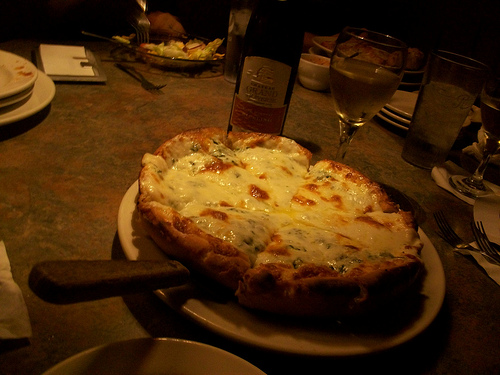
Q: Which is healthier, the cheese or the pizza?
A: The cheese is healthier than the pizza.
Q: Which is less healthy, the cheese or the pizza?
A: The pizza is less healthy than the cheese.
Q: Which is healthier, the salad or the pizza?
A: The salad is healthier than the pizza.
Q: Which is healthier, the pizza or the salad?
A: The salad is healthier than the pizza.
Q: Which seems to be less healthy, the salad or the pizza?
A: The pizza is less healthy than the salad.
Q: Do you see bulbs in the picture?
A: No, there are no bulbs.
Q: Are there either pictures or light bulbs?
A: No, there are no light bulbs or pictures.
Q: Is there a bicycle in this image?
A: No, there are no bicycles.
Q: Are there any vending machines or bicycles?
A: No, there are no bicycles or vending machines.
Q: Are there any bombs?
A: No, there are no bombs.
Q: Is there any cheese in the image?
A: Yes, there is cheese.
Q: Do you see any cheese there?
A: Yes, there is cheese.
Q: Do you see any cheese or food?
A: Yes, there is cheese.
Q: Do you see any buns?
A: No, there are no buns.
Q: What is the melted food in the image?
A: The food is cheese.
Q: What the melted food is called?
A: The food is cheese.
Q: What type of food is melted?
A: The food is cheese.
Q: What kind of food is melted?
A: The food is cheese.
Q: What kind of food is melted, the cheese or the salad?
A: The cheese is melted.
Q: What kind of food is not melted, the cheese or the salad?
A: The salad is not melted.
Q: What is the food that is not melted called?
A: The food is salad.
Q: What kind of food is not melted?
A: The food is salad.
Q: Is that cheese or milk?
A: That is cheese.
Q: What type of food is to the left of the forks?
A: The food is cheese.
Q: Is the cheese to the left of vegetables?
A: No, the cheese is to the left of the forks.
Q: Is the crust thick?
A: Yes, the crust is thick.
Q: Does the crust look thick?
A: Yes, the crust is thick.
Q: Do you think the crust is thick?
A: Yes, the crust is thick.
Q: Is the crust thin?
A: No, the crust is thick.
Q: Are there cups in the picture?
A: Yes, there is a cup.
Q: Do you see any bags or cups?
A: Yes, there is a cup.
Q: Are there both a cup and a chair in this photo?
A: No, there is a cup but no chairs.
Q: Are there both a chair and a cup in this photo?
A: No, there is a cup but no chairs.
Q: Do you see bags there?
A: No, there are no bags.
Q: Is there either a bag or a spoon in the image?
A: No, there are no bags or spoons.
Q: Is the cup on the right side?
A: Yes, the cup is on the right of the image.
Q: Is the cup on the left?
A: No, the cup is on the right of the image.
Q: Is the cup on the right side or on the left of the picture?
A: The cup is on the right of the image.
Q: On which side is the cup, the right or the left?
A: The cup is on the right of the image.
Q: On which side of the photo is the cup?
A: The cup is on the right of the image.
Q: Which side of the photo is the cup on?
A: The cup is on the right of the image.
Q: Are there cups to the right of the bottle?
A: Yes, there is a cup to the right of the bottle.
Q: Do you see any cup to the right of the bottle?
A: Yes, there is a cup to the right of the bottle.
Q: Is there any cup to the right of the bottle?
A: Yes, there is a cup to the right of the bottle.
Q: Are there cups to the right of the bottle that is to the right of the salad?
A: Yes, there is a cup to the right of the bottle.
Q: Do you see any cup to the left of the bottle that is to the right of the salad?
A: No, the cup is to the right of the bottle.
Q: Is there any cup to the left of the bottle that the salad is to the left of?
A: No, the cup is to the right of the bottle.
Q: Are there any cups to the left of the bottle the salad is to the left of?
A: No, the cup is to the right of the bottle.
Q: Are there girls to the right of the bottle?
A: No, there is a cup to the right of the bottle.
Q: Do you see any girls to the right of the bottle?
A: No, there is a cup to the right of the bottle.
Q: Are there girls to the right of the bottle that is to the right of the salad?
A: No, there is a cup to the right of the bottle.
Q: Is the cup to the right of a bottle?
A: Yes, the cup is to the right of a bottle.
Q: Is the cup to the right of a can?
A: No, the cup is to the right of a bottle.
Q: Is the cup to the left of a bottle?
A: No, the cup is to the right of a bottle.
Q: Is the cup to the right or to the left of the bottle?
A: The cup is to the right of the bottle.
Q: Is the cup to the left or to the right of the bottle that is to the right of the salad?
A: The cup is to the right of the bottle.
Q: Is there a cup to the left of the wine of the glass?
A: No, the cup is to the right of the wine.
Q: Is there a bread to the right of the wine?
A: No, there is a cup to the right of the wine.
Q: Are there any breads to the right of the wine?
A: No, there is a cup to the right of the wine.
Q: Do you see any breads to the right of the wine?
A: No, there is a cup to the right of the wine.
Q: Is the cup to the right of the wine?
A: Yes, the cup is to the right of the wine.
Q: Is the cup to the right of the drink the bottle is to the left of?
A: Yes, the cup is to the right of the wine.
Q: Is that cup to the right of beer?
A: No, the cup is to the right of the wine.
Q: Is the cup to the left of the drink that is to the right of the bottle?
A: No, the cup is to the right of the wine.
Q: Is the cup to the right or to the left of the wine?
A: The cup is to the right of the wine.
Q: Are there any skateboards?
A: No, there are no skateboards.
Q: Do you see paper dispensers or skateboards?
A: No, there are no skateboards or paper dispensers.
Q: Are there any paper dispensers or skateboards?
A: No, there are no skateboards or paper dispensers.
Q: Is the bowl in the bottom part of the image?
A: Yes, the bowl is in the bottom of the image.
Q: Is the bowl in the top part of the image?
A: No, the bowl is in the bottom of the image.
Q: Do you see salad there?
A: Yes, there is salad.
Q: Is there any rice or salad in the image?
A: Yes, there is salad.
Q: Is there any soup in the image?
A: No, there is no soup.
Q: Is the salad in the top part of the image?
A: Yes, the salad is in the top of the image.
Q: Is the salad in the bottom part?
A: No, the salad is in the top of the image.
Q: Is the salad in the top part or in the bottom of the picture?
A: The salad is in the top of the image.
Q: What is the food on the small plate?
A: The food is salad.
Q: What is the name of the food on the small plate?
A: The food is salad.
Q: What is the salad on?
A: The salad is on the plate.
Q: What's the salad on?
A: The salad is on the plate.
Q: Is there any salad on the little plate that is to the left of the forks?
A: Yes, there is salad on the plate.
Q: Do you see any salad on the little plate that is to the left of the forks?
A: Yes, there is salad on the plate.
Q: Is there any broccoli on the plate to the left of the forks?
A: No, there is salad on the plate.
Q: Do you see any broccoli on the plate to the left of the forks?
A: No, there is salad on the plate.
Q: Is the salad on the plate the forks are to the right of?
A: Yes, the salad is on the plate.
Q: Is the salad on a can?
A: No, the salad is on the plate.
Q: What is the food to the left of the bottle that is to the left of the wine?
A: The food is salad.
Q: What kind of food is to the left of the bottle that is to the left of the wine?
A: The food is salad.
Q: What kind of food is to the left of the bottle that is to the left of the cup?
A: The food is salad.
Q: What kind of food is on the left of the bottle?
A: The food is salad.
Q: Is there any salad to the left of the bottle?
A: Yes, there is salad to the left of the bottle.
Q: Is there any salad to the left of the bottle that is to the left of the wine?
A: Yes, there is salad to the left of the bottle.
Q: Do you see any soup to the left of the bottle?
A: No, there is salad to the left of the bottle.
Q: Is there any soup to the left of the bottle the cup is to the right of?
A: No, there is salad to the left of the bottle.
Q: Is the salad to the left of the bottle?
A: Yes, the salad is to the left of the bottle.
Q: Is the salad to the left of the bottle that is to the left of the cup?
A: Yes, the salad is to the left of the bottle.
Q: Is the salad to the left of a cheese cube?
A: No, the salad is to the left of the bottle.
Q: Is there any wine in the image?
A: Yes, there is wine.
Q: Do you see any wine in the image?
A: Yes, there is wine.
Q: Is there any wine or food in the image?
A: Yes, there is wine.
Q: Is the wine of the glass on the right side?
A: Yes, the wine is on the right of the image.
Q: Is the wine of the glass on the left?
A: No, the wine is on the right of the image.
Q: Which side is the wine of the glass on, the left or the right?
A: The wine is on the right of the image.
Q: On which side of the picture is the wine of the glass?
A: The wine is on the right of the image.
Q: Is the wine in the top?
A: Yes, the wine is in the top of the image.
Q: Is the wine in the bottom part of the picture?
A: No, the wine is in the top of the image.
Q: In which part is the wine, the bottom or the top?
A: The wine is in the top of the image.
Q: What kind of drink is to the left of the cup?
A: The drink is wine.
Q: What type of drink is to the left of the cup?
A: The drink is wine.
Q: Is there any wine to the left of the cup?
A: Yes, there is wine to the left of the cup.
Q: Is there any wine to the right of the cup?
A: No, the wine is to the left of the cup.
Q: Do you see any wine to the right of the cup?
A: No, the wine is to the left of the cup.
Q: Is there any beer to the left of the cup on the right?
A: No, there is wine to the left of the cup.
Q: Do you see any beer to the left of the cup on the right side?
A: No, there is wine to the left of the cup.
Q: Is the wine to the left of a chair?
A: No, the wine is to the left of the cup.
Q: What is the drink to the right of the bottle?
A: The drink is wine.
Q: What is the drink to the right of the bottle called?
A: The drink is wine.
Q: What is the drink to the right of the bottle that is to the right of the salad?
A: The drink is wine.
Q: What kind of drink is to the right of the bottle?
A: The drink is wine.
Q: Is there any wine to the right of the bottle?
A: Yes, there is wine to the right of the bottle.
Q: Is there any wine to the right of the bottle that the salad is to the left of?
A: Yes, there is wine to the right of the bottle.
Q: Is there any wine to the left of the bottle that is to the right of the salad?
A: No, the wine is to the right of the bottle.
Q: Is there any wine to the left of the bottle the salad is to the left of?
A: No, the wine is to the right of the bottle.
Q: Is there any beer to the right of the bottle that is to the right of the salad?
A: No, there is wine to the right of the bottle.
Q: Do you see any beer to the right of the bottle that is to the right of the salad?
A: No, there is wine to the right of the bottle.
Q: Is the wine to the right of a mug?
A: No, the wine is to the right of the bottle.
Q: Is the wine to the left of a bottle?
A: No, the wine is to the right of a bottle.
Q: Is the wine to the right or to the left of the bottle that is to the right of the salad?
A: The wine is to the right of the bottle.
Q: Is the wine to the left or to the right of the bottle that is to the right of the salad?
A: The wine is to the right of the bottle.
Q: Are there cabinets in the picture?
A: No, there are no cabinets.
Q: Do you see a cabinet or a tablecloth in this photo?
A: No, there are no cabinets or tablecloths.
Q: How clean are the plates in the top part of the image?
A: The plates are dirty.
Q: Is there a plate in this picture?
A: Yes, there is a plate.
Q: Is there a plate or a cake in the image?
A: Yes, there is a plate.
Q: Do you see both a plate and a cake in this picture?
A: No, there is a plate but no cakes.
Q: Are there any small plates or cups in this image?
A: Yes, there is a small plate.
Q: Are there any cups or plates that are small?
A: Yes, the plate is small.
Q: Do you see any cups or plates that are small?
A: Yes, the plate is small.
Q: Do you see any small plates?
A: Yes, there is a small plate.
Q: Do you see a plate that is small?
A: Yes, there is a plate that is small.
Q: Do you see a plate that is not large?
A: Yes, there is a small plate.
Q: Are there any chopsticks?
A: No, there are no chopsticks.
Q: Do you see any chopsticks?
A: No, there are no chopsticks.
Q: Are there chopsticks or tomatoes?
A: No, there are no chopsticks or tomatoes.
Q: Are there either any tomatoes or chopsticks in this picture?
A: No, there are no chopsticks or tomatoes.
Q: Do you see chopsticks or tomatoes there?
A: No, there are no chopsticks or tomatoes.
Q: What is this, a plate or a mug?
A: This is a plate.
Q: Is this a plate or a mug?
A: This is a plate.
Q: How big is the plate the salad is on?
A: The plate is small.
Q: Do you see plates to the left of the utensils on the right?
A: Yes, there is a plate to the left of the forks.